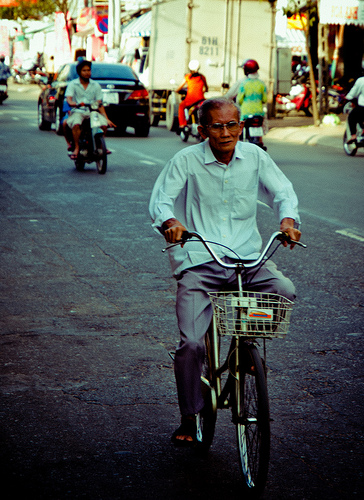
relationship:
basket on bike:
[205, 284, 312, 335] [178, 208, 311, 449]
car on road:
[39, 51, 173, 148] [6, 86, 362, 411]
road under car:
[6, 86, 362, 411] [39, 51, 173, 148]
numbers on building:
[188, 34, 227, 73] [115, 8, 303, 113]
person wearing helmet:
[227, 56, 286, 147] [239, 53, 269, 78]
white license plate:
[103, 89, 118, 98] [95, 88, 131, 108]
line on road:
[122, 137, 354, 251] [6, 86, 362, 411]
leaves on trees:
[17, 3, 46, 17] [2, 1, 78, 28]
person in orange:
[227, 56, 286, 147] [171, 73, 218, 114]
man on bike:
[149, 107, 333, 370] [178, 208, 311, 449]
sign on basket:
[244, 304, 277, 321] [205, 284, 312, 335]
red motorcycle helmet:
[240, 55, 262, 75] [239, 53, 269, 78]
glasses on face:
[198, 117, 245, 133] [198, 104, 242, 144]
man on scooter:
[149, 107, 333, 370] [60, 98, 132, 170]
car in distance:
[39, 51, 173, 148] [45, 76, 109, 107]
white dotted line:
[103, 89, 118, 98] [106, 133, 363, 258]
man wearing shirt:
[149, 107, 333, 370] [148, 144, 305, 268]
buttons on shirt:
[209, 170, 238, 197] [148, 144, 305, 268]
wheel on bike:
[207, 328, 304, 490] [178, 208, 311, 449]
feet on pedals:
[160, 417, 194, 447] [156, 357, 298, 450]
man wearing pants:
[149, 107, 333, 370] [161, 257, 301, 373]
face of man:
[198, 104, 242, 144] [149, 107, 333, 370]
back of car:
[77, 80, 169, 110] [39, 51, 173, 148]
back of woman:
[77, 80, 169, 110] [227, 56, 286, 147]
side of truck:
[96, 16, 174, 102] [115, 8, 303, 113]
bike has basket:
[178, 208, 311, 449] [205, 284, 312, 335]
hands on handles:
[155, 211, 190, 243] [138, 211, 315, 269]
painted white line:
[134, 145, 198, 192] [106, 133, 363, 258]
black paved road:
[37, 191, 136, 337] [6, 86, 362, 411]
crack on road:
[72, 217, 139, 278] [6, 86, 362, 411]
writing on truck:
[191, 34, 216, 66] [115, 8, 303, 113]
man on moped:
[149, 107, 333, 370] [60, 98, 132, 170]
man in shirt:
[149, 107, 333, 370] [148, 144, 305, 268]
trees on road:
[2, 1, 78, 28] [6, 86, 362, 411]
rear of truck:
[173, 8, 278, 111] [115, 8, 303, 113]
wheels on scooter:
[54, 122, 136, 176] [60, 98, 132, 170]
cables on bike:
[190, 230, 253, 273] [178, 208, 311, 449]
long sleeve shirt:
[134, 152, 204, 224] [148, 144, 305, 268]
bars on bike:
[138, 211, 315, 269] [178, 208, 311, 449]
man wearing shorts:
[149, 107, 333, 370] [61, 106, 122, 138]